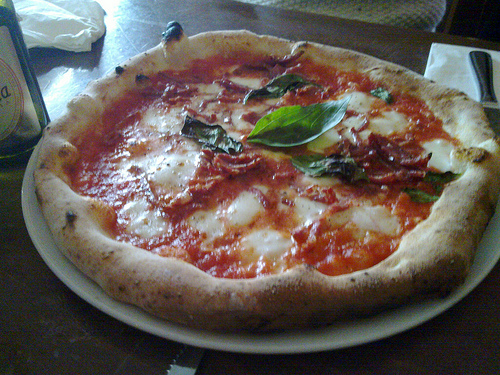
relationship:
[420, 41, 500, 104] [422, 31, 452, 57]
napkin has corner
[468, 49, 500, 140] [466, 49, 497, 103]
knife has handle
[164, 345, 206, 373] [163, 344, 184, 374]
knife has blade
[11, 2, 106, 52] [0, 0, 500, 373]
napkin on table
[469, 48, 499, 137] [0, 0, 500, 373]
knife on table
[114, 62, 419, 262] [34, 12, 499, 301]
mozzarella melted into pizza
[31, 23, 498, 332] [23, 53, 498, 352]
pizza on plate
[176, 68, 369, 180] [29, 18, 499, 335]
basil on pizza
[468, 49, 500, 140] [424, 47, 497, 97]
knife on napkin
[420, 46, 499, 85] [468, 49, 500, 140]
napkin under knife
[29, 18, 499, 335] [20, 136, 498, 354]
pizza on plate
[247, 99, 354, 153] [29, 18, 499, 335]
leaf on pizza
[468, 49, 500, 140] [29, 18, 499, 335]
knife by pizza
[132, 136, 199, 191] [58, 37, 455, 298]
white mozzerella on pizza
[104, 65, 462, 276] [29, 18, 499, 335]
cheese on pizza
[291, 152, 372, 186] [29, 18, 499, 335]
basil on pizza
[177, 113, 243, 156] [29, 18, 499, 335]
basil on pizza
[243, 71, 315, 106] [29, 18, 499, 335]
basil on pizza